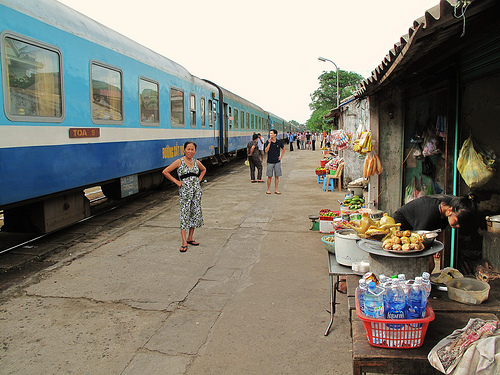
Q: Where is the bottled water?
A: In a red basket.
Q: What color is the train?
A: Blue and white.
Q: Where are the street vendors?
A: At a train stop.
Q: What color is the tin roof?
A: Brown.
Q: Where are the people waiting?
A: On platform in front of train.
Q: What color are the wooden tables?
A: Brown.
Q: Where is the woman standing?
A: In the sidewalk near train.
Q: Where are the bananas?
A: On the wall.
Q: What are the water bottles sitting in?
A: Laundry basket.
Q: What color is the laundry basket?
A: Red.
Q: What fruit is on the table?
A: Bananas.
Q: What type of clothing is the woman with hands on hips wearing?
A: Dress.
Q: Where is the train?
A: On the tracks.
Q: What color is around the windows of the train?
A: Light blue.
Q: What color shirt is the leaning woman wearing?
A: Black.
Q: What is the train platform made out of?
A: Concrete.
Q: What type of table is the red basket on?
A: Wooden.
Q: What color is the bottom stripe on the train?
A: Dark blue.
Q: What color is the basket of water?
A: Red.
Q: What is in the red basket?
A: Water bottles.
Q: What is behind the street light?
A: A tree.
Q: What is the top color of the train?
A: Blue.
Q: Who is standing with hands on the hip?
A: A lady.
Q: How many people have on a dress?
A: One.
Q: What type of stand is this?
A: Fruit.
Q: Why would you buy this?
A: Hungry.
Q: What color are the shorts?
A: Gray.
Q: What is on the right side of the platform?
A: Vendors.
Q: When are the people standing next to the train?
A: Now.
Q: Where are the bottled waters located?
A: In a basket.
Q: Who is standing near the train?
A: People.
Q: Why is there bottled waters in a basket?
A: To be sold.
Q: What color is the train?
A: Blue.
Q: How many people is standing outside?
A: Over ten people.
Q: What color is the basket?
A: Pink.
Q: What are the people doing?
A: Standing near the the train.